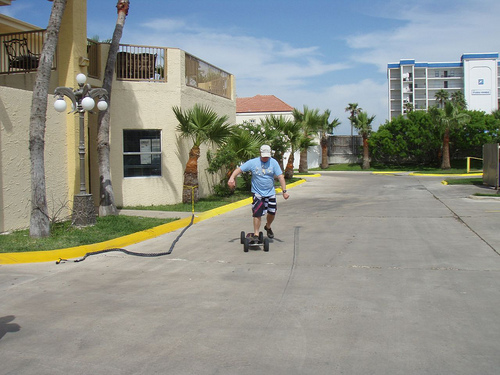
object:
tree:
[171, 103, 235, 204]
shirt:
[239, 158, 283, 199]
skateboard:
[239, 229, 269, 252]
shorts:
[252, 192, 277, 217]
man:
[226, 145, 292, 243]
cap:
[260, 141, 271, 160]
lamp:
[55, 73, 112, 226]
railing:
[1, 29, 231, 99]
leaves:
[167, 102, 236, 144]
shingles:
[234, 94, 296, 115]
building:
[387, 52, 499, 123]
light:
[54, 99, 69, 113]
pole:
[53, 86, 113, 227]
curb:
[1, 179, 233, 278]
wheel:
[240, 229, 248, 244]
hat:
[261, 144, 273, 159]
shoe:
[262, 225, 274, 241]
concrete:
[0, 258, 500, 374]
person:
[225, 144, 289, 238]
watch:
[280, 187, 289, 195]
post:
[53, 86, 114, 225]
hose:
[50, 198, 196, 271]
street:
[2, 172, 498, 374]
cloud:
[100, 15, 355, 94]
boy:
[225, 144, 290, 236]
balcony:
[1, 30, 244, 100]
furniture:
[2, 37, 198, 82]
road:
[1, 172, 499, 375]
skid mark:
[283, 223, 307, 293]